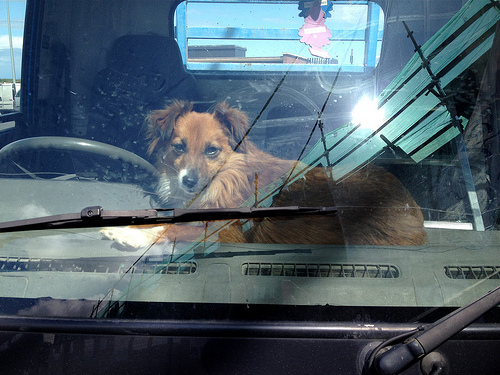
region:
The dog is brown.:
[81, 50, 428, 279]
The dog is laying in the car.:
[112, 92, 440, 276]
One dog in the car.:
[78, 86, 437, 258]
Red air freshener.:
[289, 3, 349, 67]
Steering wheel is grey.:
[1, 92, 158, 196]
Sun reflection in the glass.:
[330, 77, 390, 147]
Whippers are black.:
[1, 175, 317, 234]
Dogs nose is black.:
[170, 167, 203, 200]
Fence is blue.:
[142, 0, 400, 82]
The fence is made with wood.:
[157, 5, 424, 82]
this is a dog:
[146, 108, 430, 248]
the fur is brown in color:
[231, 147, 258, 173]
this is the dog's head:
[144, 89, 241, 199]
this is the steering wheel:
[3, 137, 150, 179]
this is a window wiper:
[50, 203, 336, 220]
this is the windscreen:
[36, 16, 498, 91]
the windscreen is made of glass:
[241, 25, 424, 120]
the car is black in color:
[92, 334, 186, 373]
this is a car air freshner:
[299, 5, 336, 57]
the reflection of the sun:
[347, 85, 399, 130]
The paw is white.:
[100, 213, 177, 245]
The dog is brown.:
[234, 159, 280, 186]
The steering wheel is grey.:
[42, 134, 91, 159]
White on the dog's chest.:
[144, 180, 178, 206]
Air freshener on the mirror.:
[308, 31, 339, 55]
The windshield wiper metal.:
[115, 207, 179, 238]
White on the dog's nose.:
[170, 171, 194, 198]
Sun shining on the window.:
[318, 87, 405, 138]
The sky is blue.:
[206, 7, 253, 32]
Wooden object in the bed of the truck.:
[248, 54, 297, 78]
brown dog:
[96, 99, 438, 286]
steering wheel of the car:
[1, 126, 161, 197]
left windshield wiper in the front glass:
[0, 200, 360, 230]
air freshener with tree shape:
[292, 0, 337, 60]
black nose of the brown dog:
[180, 172, 195, 184]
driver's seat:
[65, 30, 210, 200]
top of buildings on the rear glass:
[150, 40, 350, 71]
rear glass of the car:
[160, 0, 390, 75]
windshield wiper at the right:
[352, 235, 494, 368]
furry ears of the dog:
[134, 91, 262, 161]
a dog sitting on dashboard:
[94, 77, 441, 256]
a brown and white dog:
[96, 100, 431, 257]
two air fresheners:
[290, 1, 342, 67]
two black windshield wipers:
[2, 197, 495, 373]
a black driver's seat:
[79, 25, 214, 199]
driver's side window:
[0, 0, 34, 139]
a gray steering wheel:
[0, 126, 157, 192]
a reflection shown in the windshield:
[87, 0, 499, 315]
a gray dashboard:
[2, 174, 497, 305]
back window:
[162, 3, 398, 83]